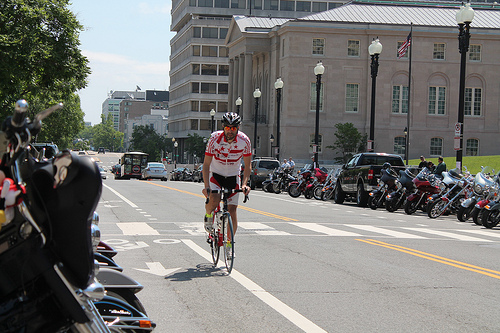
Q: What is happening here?
A: Bike riding.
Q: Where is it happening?
A: On the street.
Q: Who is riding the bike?
A: A guy.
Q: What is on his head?
A: Helmet.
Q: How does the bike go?
A: Pedals.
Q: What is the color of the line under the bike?
A: White.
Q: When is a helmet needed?
A: At all times on a bike.